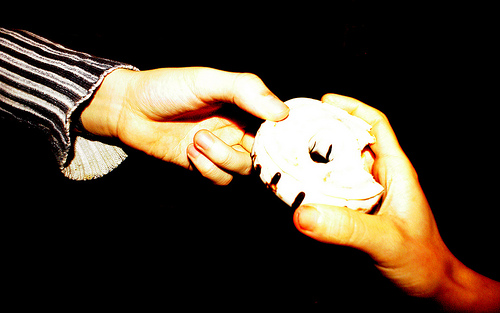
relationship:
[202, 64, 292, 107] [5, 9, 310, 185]
thumb of person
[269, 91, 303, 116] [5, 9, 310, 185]
nail of person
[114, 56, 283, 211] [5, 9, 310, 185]
hand of person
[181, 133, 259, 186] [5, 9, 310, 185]
finger of person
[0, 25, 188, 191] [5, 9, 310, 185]
arm of person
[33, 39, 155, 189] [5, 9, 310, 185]
wrist of person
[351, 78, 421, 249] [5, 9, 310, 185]
knuckle of person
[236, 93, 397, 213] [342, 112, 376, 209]
donut has bite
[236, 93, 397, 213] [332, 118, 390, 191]
donut has part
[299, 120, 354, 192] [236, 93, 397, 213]
icing on donut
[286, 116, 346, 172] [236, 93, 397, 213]
hole in donut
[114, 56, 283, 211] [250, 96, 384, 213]
hand grasping donut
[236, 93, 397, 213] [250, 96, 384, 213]
hole in middle of donut